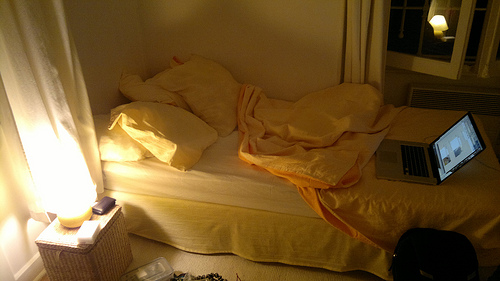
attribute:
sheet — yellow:
[239, 81, 498, 266]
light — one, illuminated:
[421, 7, 451, 38]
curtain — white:
[0, 4, 103, 208]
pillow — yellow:
[119, 103, 200, 167]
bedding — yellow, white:
[235, 83, 499, 263]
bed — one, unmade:
[95, 53, 496, 276]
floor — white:
[131, 236, 379, 279]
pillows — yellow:
[151, 53, 243, 135]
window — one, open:
[385, 2, 460, 64]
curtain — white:
[9, 0, 115, 216]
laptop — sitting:
[370, 110, 482, 186]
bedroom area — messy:
[67, 50, 484, 249]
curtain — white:
[0, 2, 111, 222]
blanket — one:
[234, 80, 499, 267]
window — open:
[380, 3, 483, 101]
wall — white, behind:
[136, 3, 346, 102]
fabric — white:
[14, 88, 44, 120]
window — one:
[383, 11, 493, 97]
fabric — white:
[23, 57, 86, 154]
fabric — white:
[5, 2, 115, 208]